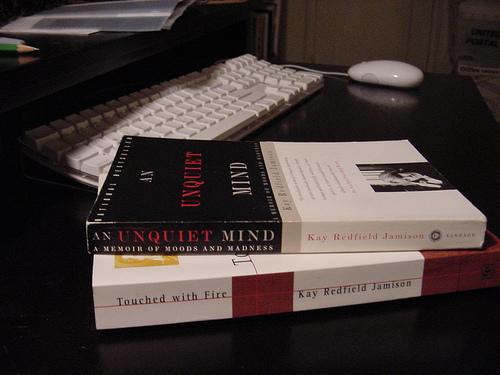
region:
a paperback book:
[82, 132, 486, 249]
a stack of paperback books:
[77, 131, 487, 348]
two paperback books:
[70, 118, 485, 343]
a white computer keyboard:
[32, 50, 326, 190]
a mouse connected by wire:
[270, 51, 431, 88]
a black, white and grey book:
[87, 135, 487, 260]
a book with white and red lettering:
[85, 133, 486, 257]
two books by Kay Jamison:
[83, 133, 493, 339]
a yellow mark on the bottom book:
[108, 254, 189, 276]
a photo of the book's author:
[351, 156, 454, 199]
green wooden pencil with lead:
[2, 26, 50, 64]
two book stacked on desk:
[95, 123, 458, 353]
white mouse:
[332, 40, 442, 113]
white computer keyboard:
[7, 43, 301, 168]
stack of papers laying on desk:
[3, 1, 204, 50]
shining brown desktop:
[326, 57, 493, 125]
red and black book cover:
[130, 136, 276, 246]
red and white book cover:
[100, 258, 497, 344]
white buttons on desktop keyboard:
[139, 76, 282, 133]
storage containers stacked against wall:
[435, 3, 498, 84]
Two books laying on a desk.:
[68, 117, 456, 354]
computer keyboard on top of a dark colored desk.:
[31, 50, 321, 175]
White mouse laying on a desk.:
[311, 57, 440, 91]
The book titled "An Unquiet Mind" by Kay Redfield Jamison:
[74, 144, 494, 261]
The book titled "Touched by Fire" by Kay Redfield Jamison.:
[63, 242, 482, 339]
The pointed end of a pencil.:
[1, 36, 47, 59]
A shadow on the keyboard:
[22, 91, 184, 142]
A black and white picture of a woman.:
[370, 160, 427, 197]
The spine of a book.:
[90, 216, 490, 253]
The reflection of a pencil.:
[0, 51, 39, 69]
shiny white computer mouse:
[347, 49, 435, 91]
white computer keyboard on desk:
[52, 46, 332, 186]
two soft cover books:
[74, 114, 481, 342]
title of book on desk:
[108, 283, 234, 322]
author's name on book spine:
[284, 267, 421, 312]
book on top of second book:
[84, 126, 486, 260]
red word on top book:
[178, 144, 215, 221]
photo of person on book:
[355, 157, 445, 202]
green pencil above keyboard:
[2, 33, 42, 56]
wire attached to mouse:
[272, 56, 370, 79]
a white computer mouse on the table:
[346, 49, 421, 96]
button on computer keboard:
[154, 72, 280, 130]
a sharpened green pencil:
[5, 38, 32, 57]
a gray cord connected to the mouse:
[293, 60, 343, 77]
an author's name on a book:
[297, 280, 444, 296]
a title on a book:
[94, 226, 282, 247]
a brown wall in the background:
[300, 11, 405, 44]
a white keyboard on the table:
[59, 64, 290, 123]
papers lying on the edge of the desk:
[58, 15, 173, 37]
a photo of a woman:
[360, 159, 464, 206]